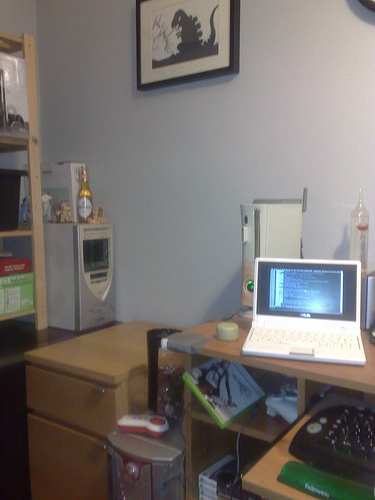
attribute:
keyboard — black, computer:
[300, 405, 373, 459]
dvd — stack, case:
[178, 356, 281, 427]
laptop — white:
[243, 253, 366, 365]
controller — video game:
[266, 381, 306, 424]